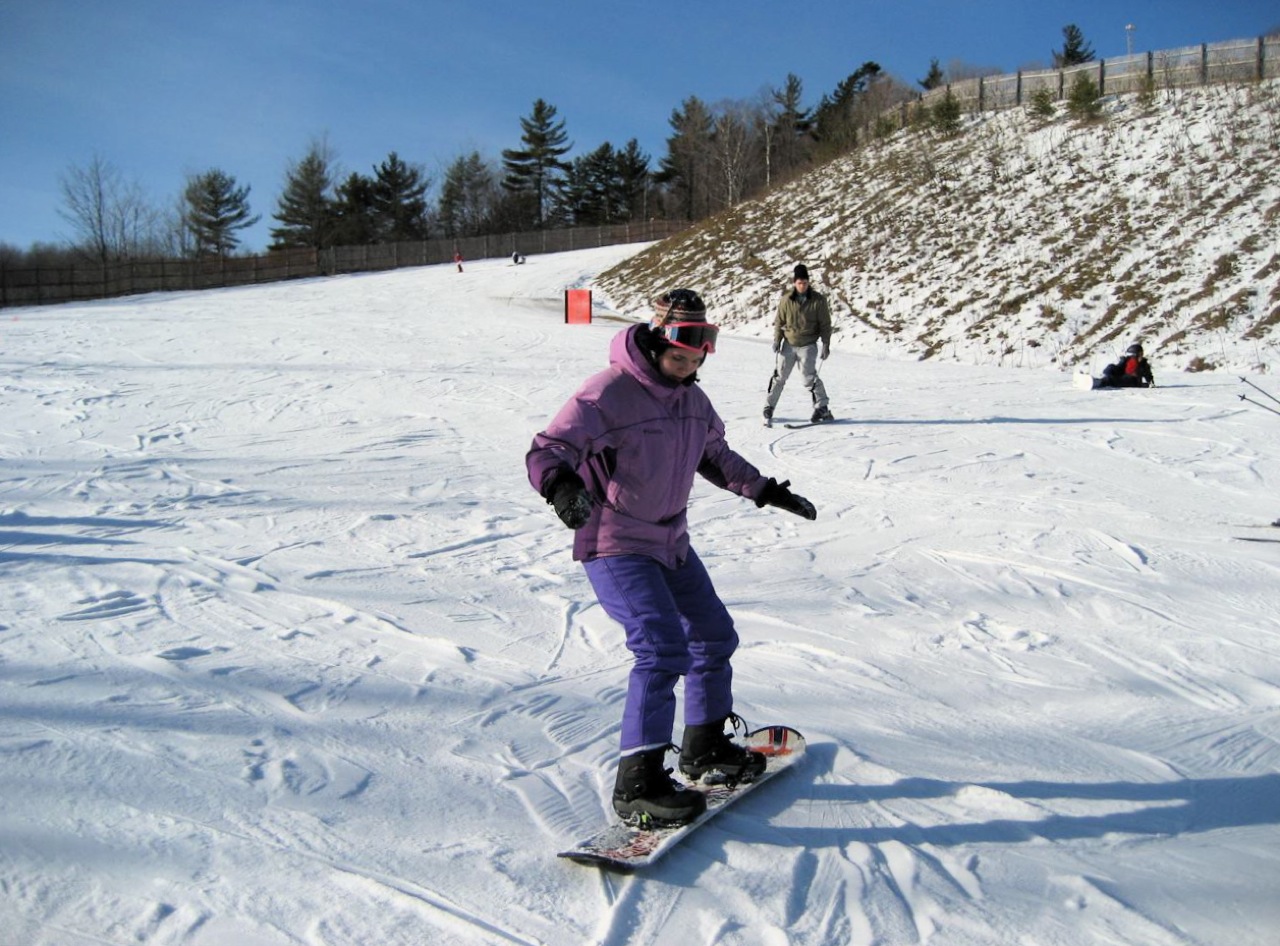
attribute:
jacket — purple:
[526, 316, 775, 558]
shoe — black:
[603, 747, 712, 826]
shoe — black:
[666, 712, 768, 784]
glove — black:
[729, 474, 831, 522]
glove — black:
[522, 460, 622, 536]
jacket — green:
[768, 286, 833, 348]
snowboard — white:
[561, 714, 805, 872]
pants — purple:
[587, 540, 740, 763]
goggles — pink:
[636, 314, 726, 355]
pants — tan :
[764, 349, 836, 418]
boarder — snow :
[503, 281, 849, 918]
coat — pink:
[515, 318, 771, 569]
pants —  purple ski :
[580, 542, 756, 779]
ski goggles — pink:
[630, 323, 723, 346]